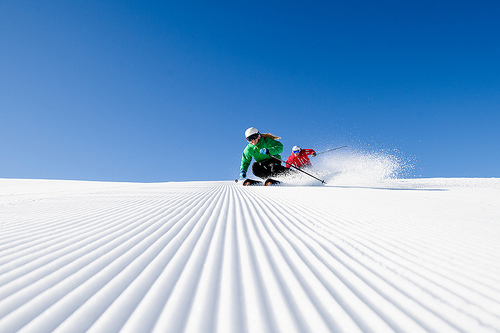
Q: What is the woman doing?
A: Skiing.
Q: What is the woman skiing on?
A: The snow.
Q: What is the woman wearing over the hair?
A: A hat.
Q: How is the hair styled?
A: In a ponytail.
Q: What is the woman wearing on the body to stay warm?
A: A coat.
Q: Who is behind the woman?
A: A man.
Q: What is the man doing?
A: Skiing.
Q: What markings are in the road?
A: Trail lines.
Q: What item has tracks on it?
A: The snow.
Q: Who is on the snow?
A: Skiers.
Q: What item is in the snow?
A: Lines.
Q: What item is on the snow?
A: Lines.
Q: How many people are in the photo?
A: Two.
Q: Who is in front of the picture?
A: A women.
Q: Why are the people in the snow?
A: Skiing.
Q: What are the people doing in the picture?
A: Skiing.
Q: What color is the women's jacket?
A: Green.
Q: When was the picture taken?
A: During the day.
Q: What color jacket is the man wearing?
A: Red.